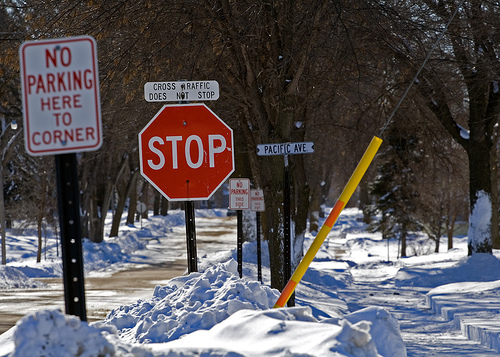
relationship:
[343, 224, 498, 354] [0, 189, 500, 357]
sidewalk covered in snow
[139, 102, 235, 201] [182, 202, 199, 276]
letter on post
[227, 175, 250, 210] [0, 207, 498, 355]
sign on snow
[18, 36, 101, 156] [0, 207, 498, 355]
letters on snow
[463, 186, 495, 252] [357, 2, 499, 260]
snow on tree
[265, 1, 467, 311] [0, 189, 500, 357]
wire above snow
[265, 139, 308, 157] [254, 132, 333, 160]
pacific ave on sign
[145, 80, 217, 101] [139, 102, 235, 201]
parking signs on letter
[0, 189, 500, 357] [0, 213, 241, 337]
snow on road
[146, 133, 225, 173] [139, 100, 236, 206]
letter on sign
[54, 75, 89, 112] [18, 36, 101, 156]
letters on letters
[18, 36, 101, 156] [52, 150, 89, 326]
letters on pole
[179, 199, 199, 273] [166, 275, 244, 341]
pole sticking in snow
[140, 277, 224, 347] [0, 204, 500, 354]
snow covering ground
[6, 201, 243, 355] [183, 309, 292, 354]
pavement cleared of snow